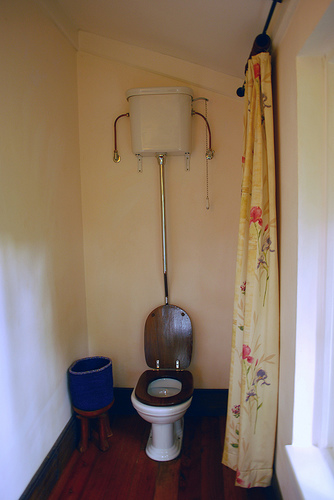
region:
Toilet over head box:
[126, 84, 190, 153]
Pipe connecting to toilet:
[151, 150, 171, 300]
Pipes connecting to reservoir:
[107, 109, 133, 161]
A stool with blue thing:
[62, 344, 118, 448]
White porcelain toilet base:
[132, 393, 190, 459]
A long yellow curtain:
[221, 33, 282, 489]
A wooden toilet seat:
[134, 300, 193, 406]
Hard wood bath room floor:
[51, 417, 266, 497]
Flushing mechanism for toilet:
[189, 88, 214, 219]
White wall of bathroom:
[8, 8, 247, 386]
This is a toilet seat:
[124, 357, 197, 471]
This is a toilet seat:
[128, 402, 209, 468]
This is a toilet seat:
[117, 286, 218, 405]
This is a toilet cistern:
[95, 70, 240, 203]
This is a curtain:
[226, 47, 287, 476]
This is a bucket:
[59, 337, 119, 411]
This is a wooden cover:
[139, 296, 203, 371]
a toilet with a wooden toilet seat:
[131, 303, 195, 461]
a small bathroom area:
[0, 4, 332, 498]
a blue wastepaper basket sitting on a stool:
[66, 353, 114, 411]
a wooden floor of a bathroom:
[47, 410, 284, 498]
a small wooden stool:
[69, 404, 118, 453]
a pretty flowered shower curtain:
[220, 51, 275, 488]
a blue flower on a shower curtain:
[242, 385, 265, 434]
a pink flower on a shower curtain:
[248, 202, 265, 260]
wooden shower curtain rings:
[240, 35, 271, 84]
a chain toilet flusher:
[203, 99, 212, 210]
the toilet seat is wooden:
[131, 301, 193, 408]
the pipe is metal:
[146, 179, 174, 300]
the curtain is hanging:
[230, 229, 283, 488]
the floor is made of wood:
[82, 455, 127, 494]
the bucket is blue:
[65, 345, 114, 406]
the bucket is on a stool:
[65, 341, 125, 457]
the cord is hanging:
[196, 93, 225, 213]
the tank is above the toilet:
[119, 69, 206, 162]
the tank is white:
[106, 73, 205, 157]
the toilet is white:
[132, 401, 198, 461]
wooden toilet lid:
[140, 304, 205, 367]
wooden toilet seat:
[138, 368, 195, 413]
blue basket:
[64, 352, 122, 413]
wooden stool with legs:
[71, 397, 122, 456]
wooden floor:
[62, 452, 164, 498]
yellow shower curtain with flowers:
[239, 97, 276, 416]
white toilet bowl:
[128, 406, 194, 442]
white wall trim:
[73, 35, 244, 91]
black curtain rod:
[222, 2, 269, 111]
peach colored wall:
[96, 200, 151, 300]